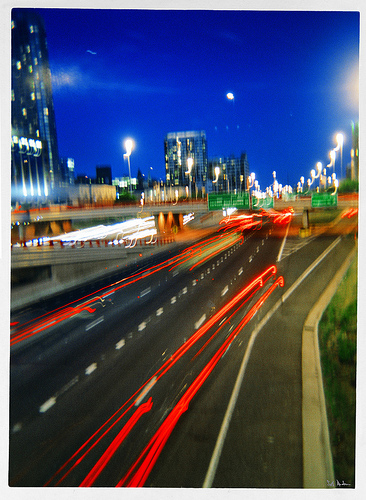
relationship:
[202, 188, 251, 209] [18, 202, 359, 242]
sign over bridge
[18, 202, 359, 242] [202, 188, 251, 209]
bridge has sign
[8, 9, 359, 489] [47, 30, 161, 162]
light in sky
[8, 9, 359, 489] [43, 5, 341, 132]
light in sky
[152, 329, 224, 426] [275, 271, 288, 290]
breaklights from cars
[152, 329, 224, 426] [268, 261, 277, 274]
breaklights from cars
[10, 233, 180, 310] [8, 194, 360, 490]
ramp to highway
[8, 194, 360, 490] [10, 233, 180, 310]
highway has a ramp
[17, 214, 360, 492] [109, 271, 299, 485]
highway a road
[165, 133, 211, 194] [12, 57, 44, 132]
building has windows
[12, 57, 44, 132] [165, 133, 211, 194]
windows on a building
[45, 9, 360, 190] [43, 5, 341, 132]
clouds in sky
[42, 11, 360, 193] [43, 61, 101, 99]
sky has clouds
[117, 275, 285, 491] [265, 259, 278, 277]
light from car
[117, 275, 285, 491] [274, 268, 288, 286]
light from car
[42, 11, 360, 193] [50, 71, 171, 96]
sky has clouds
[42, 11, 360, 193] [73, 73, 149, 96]
sky has clouds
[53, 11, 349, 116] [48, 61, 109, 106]
sky has clouds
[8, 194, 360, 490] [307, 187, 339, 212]
highway has sign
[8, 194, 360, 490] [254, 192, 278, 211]
highway has sign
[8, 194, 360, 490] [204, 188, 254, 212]
highway has sign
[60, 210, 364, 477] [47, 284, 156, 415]
road has lines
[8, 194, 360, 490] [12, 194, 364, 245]
highway has bridge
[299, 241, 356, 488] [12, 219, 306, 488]
edge on road